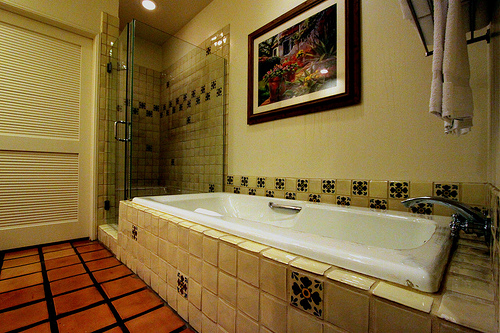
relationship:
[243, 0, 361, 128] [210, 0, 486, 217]
painting hanging on wall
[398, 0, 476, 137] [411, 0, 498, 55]
towel on rack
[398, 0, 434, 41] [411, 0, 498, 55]
towel on rack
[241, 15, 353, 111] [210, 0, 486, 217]
painting on wall